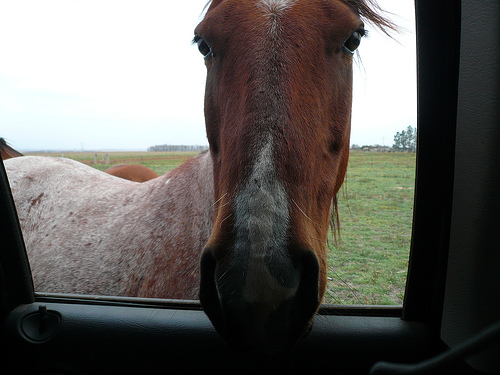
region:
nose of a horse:
[281, 266, 319, 316]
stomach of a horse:
[47, 240, 97, 285]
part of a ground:
[356, 214, 393, 281]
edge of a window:
[78, 289, 124, 326]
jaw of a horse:
[333, 149, 357, 199]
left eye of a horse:
[348, 21, 367, 66]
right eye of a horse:
[192, 30, 216, 71]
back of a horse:
[87, 171, 145, 212]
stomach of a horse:
[40, 252, 92, 300]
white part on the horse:
[246, 242, 276, 284]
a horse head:
[145, 10, 388, 347]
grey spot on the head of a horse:
[223, 121, 302, 257]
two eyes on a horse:
[182, 16, 380, 64]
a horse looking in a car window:
[20, 11, 466, 366]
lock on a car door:
[25, 293, 67, 340]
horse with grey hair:
[7, 146, 334, 316]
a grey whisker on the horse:
[284, 187, 322, 229]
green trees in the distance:
[385, 116, 424, 153]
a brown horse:
[186, 6, 381, 328]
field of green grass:
[335, 165, 415, 292]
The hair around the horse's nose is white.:
[221, 139, 293, 302]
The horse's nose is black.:
[180, 245, 335, 355]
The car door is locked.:
[18, 299, 60, 342]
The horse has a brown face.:
[201, 29, 366, 219]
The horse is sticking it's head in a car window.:
[5, 10, 499, 340]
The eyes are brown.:
[321, 0, 400, 85]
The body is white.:
[34, 166, 126, 281]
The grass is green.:
[338, 207, 410, 289]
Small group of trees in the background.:
[388, 116, 430, 166]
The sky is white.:
[76, 65, 215, 137]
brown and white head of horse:
[168, 10, 386, 341]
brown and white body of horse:
[28, 155, 214, 295]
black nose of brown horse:
[183, 220, 331, 338]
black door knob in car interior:
[27, 296, 69, 348]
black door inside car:
[411, 16, 458, 312]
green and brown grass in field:
[346, 195, 396, 295]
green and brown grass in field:
[356, 149, 411, 199]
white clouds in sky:
[14, 6, 159, 75]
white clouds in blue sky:
[22, 57, 188, 129]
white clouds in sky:
[368, 50, 413, 114]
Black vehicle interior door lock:
[17, 293, 78, 361]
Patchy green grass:
[363, 159, 405, 294]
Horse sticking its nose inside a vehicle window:
[21, 6, 427, 369]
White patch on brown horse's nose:
[228, 121, 305, 271]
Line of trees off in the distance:
[101, 128, 196, 156]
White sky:
[40, 30, 177, 116]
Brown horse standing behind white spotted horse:
[0, 115, 166, 202]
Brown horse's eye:
[177, 15, 227, 76]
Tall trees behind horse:
[391, 116, 418, 166]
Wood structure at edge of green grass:
[88, 149, 120, 166]